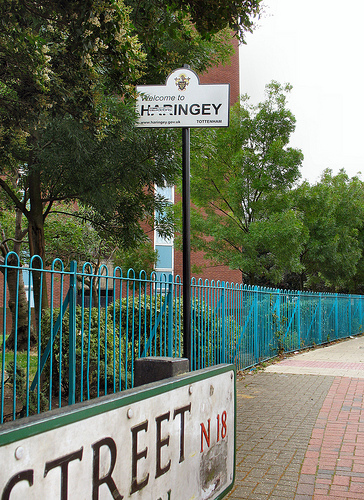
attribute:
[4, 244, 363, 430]
fence panel — metal, blue, iron, light blue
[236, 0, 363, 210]
sky — overcast, white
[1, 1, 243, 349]
wall — brick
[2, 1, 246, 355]
building — red, brick, tall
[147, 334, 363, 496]
sidewalk — brick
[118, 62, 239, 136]
sign — white, large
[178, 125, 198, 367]
pole — black, metal, tall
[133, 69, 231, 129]
trim — green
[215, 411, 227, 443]
numbers — red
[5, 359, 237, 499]
sign — white, large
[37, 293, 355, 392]
bushes — green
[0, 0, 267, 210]
leaves — bright green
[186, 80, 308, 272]
leaves — bright green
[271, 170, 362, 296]
leaves — bright green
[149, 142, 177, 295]
window — white, double hung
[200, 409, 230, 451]
lettering — red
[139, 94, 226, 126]
lettering — black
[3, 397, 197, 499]
lettering — black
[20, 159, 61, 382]
trunk — tall, brown